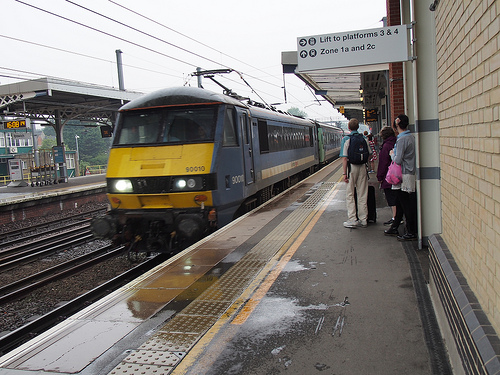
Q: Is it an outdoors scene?
A: Yes, it is outdoors.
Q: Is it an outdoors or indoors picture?
A: It is outdoors.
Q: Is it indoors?
A: No, it is outdoors.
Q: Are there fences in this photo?
A: No, there are no fences.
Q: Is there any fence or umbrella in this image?
A: No, there are no fences or umbrellas.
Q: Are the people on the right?
A: Yes, the people are on the right of the image.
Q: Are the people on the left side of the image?
A: No, the people are on the right of the image.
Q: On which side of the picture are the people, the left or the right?
A: The people are on the right of the image.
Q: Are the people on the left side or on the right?
A: The people are on the right of the image.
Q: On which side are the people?
A: The people are on the right of the image.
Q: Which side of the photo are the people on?
A: The people are on the right of the image.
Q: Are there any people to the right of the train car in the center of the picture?
A: Yes, there are people to the right of the train car.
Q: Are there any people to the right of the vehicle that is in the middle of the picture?
A: Yes, there are people to the right of the train car.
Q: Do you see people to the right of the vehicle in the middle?
A: Yes, there are people to the right of the train car.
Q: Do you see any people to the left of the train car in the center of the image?
A: No, the people are to the right of the train car.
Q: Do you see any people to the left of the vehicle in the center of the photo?
A: No, the people are to the right of the train car.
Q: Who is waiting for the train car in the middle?
A: The people are waiting for the train car.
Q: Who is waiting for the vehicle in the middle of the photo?
A: The people are waiting for the train car.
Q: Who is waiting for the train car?
A: The people are waiting for the train car.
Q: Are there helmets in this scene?
A: No, there are no helmets.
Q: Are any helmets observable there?
A: No, there are no helmets.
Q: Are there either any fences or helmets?
A: No, there are no helmets or fences.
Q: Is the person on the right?
A: Yes, the person is on the right of the image.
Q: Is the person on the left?
A: No, the person is on the right of the image.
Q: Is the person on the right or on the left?
A: The person is on the right of the image.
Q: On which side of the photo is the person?
A: The person is on the right of the image.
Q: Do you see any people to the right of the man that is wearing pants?
A: Yes, there is a person to the right of the man.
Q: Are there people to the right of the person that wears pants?
A: Yes, there is a person to the right of the man.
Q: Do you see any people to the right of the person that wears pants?
A: Yes, there is a person to the right of the man.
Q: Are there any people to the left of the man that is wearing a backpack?
A: No, the person is to the right of the man.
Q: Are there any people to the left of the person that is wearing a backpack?
A: No, the person is to the right of the man.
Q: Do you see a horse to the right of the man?
A: No, there is a person to the right of the man.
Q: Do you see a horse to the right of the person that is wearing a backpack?
A: No, there is a person to the right of the man.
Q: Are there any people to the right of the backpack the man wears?
A: Yes, there is a person to the right of the backpack.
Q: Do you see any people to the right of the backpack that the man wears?
A: Yes, there is a person to the right of the backpack.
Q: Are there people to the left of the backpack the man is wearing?
A: No, the person is to the right of the backpack.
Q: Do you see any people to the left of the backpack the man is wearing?
A: No, the person is to the right of the backpack.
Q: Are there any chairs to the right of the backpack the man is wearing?
A: No, there is a person to the right of the backpack.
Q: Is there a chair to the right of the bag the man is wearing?
A: No, there is a person to the right of the backpack.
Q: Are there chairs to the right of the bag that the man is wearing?
A: No, there is a person to the right of the backpack.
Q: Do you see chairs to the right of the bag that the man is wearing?
A: No, there is a person to the right of the backpack.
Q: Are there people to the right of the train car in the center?
A: Yes, there is a person to the right of the train car.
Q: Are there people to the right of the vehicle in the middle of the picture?
A: Yes, there is a person to the right of the train car.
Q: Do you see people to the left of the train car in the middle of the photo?
A: No, the person is to the right of the train car.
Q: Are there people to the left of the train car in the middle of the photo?
A: No, the person is to the right of the train car.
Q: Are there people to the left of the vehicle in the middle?
A: No, the person is to the right of the train car.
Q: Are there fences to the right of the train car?
A: No, there is a person to the right of the train car.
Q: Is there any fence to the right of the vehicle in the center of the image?
A: No, there is a person to the right of the train car.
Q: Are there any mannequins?
A: No, there are no mannequins.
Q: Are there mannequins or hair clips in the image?
A: No, there are no mannequins or hair clips.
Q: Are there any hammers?
A: No, there are no hammers.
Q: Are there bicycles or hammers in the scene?
A: No, there are no hammers or bicycles.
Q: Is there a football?
A: No, there are no footballs.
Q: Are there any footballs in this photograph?
A: No, there are no footballs.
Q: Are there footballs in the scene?
A: No, there are no footballs.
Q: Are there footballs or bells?
A: No, there are no footballs or bells.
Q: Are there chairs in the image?
A: No, there are no chairs.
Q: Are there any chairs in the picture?
A: No, there are no chairs.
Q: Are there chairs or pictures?
A: No, there are no chairs or pictures.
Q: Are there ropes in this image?
A: No, there are no ropes.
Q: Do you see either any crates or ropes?
A: No, there are no ropes or crates.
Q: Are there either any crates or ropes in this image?
A: No, there are no ropes or crates.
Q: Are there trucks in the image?
A: No, there are no trucks.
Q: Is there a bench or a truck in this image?
A: No, there are no trucks or benches.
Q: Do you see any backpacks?
A: Yes, there is a backpack.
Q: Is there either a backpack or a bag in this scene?
A: Yes, there is a backpack.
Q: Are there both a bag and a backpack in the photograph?
A: Yes, there are both a backpack and a bag.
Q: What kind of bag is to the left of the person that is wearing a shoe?
A: The bag is a backpack.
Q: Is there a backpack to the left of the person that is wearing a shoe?
A: Yes, there is a backpack to the left of the person.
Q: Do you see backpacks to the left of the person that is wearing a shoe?
A: Yes, there is a backpack to the left of the person.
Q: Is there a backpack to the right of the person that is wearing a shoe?
A: No, the backpack is to the left of the person.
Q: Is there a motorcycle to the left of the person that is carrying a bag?
A: No, there is a backpack to the left of the person.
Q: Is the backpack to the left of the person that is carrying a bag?
A: Yes, the backpack is to the left of the person.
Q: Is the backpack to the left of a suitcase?
A: No, the backpack is to the left of the person.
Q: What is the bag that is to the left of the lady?
A: The bag is a backpack.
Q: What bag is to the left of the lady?
A: The bag is a backpack.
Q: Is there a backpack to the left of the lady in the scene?
A: Yes, there is a backpack to the left of the lady.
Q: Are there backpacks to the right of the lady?
A: No, the backpack is to the left of the lady.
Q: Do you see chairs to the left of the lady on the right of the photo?
A: No, there is a backpack to the left of the lady.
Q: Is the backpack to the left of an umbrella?
A: No, the backpack is to the left of a lady.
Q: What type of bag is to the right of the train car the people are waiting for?
A: The bag is a backpack.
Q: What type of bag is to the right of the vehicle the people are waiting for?
A: The bag is a backpack.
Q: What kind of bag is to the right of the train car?
A: The bag is a backpack.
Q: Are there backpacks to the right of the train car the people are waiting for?
A: Yes, there is a backpack to the right of the train car.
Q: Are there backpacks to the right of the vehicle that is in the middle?
A: Yes, there is a backpack to the right of the train car.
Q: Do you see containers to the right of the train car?
A: No, there is a backpack to the right of the train car.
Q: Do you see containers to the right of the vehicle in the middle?
A: No, there is a backpack to the right of the train car.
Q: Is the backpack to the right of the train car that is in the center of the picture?
A: Yes, the backpack is to the right of the train car.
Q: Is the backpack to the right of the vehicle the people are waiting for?
A: Yes, the backpack is to the right of the train car.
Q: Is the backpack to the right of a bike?
A: No, the backpack is to the right of the train car.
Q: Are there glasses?
A: No, there are no glasses.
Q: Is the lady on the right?
A: Yes, the lady is on the right of the image.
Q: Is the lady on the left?
A: No, the lady is on the right of the image.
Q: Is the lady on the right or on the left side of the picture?
A: The lady is on the right of the image.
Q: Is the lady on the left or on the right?
A: The lady is on the right of the image.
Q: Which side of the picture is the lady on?
A: The lady is on the right of the image.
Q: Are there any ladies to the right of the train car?
A: Yes, there is a lady to the right of the train car.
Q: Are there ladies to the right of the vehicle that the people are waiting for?
A: Yes, there is a lady to the right of the train car.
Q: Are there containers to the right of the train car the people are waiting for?
A: No, there is a lady to the right of the train car.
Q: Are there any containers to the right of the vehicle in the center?
A: No, there is a lady to the right of the train car.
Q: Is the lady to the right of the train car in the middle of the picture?
A: Yes, the lady is to the right of the train car.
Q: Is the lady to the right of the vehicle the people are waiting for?
A: Yes, the lady is to the right of the train car.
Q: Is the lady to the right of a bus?
A: No, the lady is to the right of the train car.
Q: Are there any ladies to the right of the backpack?
A: Yes, there is a lady to the right of the backpack.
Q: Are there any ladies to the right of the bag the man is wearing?
A: Yes, there is a lady to the right of the backpack.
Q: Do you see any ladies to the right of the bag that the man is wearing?
A: Yes, there is a lady to the right of the backpack.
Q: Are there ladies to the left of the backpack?
A: No, the lady is to the right of the backpack.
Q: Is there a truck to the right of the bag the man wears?
A: No, there is a lady to the right of the backpack.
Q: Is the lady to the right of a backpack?
A: Yes, the lady is to the right of a backpack.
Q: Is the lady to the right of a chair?
A: No, the lady is to the right of a backpack.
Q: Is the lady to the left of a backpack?
A: No, the lady is to the right of a backpack.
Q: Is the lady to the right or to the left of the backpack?
A: The lady is to the right of the backpack.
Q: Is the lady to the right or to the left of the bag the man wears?
A: The lady is to the right of the backpack.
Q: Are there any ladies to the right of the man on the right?
A: Yes, there is a lady to the right of the man.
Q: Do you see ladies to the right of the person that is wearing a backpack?
A: Yes, there is a lady to the right of the man.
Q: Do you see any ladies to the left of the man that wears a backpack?
A: No, the lady is to the right of the man.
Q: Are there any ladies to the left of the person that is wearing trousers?
A: No, the lady is to the right of the man.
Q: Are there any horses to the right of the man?
A: No, there is a lady to the right of the man.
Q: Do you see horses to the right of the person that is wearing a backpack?
A: No, there is a lady to the right of the man.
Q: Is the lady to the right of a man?
A: Yes, the lady is to the right of a man.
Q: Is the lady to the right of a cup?
A: No, the lady is to the right of a man.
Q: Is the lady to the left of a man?
A: No, the lady is to the right of a man.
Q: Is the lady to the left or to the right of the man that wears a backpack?
A: The lady is to the right of the man.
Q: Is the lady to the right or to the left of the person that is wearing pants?
A: The lady is to the right of the man.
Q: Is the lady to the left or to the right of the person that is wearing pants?
A: The lady is to the right of the man.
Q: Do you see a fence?
A: No, there are no fences.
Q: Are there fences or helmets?
A: No, there are no fences or helmets.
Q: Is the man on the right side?
A: Yes, the man is on the right of the image.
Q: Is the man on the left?
A: No, the man is on the right of the image.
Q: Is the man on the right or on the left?
A: The man is on the right of the image.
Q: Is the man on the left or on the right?
A: The man is on the right of the image.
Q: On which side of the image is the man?
A: The man is on the right of the image.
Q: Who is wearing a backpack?
A: The man is wearing a backpack.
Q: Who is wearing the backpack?
A: The man is wearing a backpack.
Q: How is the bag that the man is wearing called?
A: The bag is a backpack.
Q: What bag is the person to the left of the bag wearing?
A: The man is wearing a backpack.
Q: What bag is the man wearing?
A: The man is wearing a backpack.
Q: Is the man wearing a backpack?
A: Yes, the man is wearing a backpack.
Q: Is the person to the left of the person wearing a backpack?
A: Yes, the man is wearing a backpack.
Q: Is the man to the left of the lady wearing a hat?
A: No, the man is wearing a backpack.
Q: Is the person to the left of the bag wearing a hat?
A: No, the man is wearing a backpack.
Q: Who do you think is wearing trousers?
A: The man is wearing trousers.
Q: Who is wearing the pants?
A: The man is wearing trousers.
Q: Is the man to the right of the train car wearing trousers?
A: Yes, the man is wearing trousers.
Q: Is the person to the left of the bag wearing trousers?
A: Yes, the man is wearing trousers.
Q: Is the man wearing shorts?
A: No, the man is wearing trousers.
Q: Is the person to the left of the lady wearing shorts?
A: No, the man is wearing trousers.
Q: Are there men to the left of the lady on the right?
A: Yes, there is a man to the left of the lady.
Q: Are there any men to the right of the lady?
A: No, the man is to the left of the lady.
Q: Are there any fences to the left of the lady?
A: No, there is a man to the left of the lady.